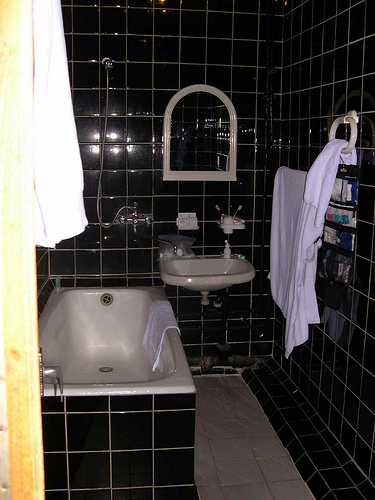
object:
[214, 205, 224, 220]
tooth brush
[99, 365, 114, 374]
drain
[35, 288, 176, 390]
bath tub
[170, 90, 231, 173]
mirror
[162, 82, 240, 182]
frame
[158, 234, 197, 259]
bag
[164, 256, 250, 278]
sink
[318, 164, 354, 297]
organizer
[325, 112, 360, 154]
hanger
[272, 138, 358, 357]
bath towel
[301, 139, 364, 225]
hand towel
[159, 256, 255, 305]
basin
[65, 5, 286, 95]
tiled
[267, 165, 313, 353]
towel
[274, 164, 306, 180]
rack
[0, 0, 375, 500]
bathroom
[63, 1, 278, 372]
wall